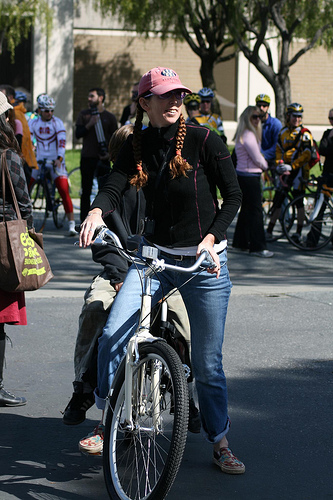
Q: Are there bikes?
A: Yes, there is a bike.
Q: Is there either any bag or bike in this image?
A: Yes, there is a bike.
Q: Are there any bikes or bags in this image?
A: Yes, there is a bike.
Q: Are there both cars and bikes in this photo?
A: No, there is a bike but no cars.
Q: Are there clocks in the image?
A: No, there are no clocks.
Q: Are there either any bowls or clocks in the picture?
A: No, there are no clocks or bowls.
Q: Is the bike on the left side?
A: Yes, the bike is on the left of the image.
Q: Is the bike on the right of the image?
A: No, the bike is on the left of the image.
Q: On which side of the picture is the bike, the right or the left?
A: The bike is on the left of the image.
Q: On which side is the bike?
A: The bike is on the left of the image.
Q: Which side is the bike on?
A: The bike is on the left of the image.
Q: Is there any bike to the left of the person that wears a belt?
A: Yes, there is a bike to the left of the person.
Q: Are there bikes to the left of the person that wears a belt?
A: Yes, there is a bike to the left of the person.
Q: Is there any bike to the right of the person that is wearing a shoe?
A: No, the bike is to the left of the person.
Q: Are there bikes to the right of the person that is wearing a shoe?
A: No, the bike is to the left of the person.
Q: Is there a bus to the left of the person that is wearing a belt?
A: No, there is a bike to the left of the person.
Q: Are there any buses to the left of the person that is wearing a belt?
A: No, there is a bike to the left of the person.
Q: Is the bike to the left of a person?
A: Yes, the bike is to the left of a person.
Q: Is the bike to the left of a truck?
A: No, the bike is to the left of a person.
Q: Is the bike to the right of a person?
A: No, the bike is to the left of a person.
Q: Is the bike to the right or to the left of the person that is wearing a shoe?
A: The bike is to the left of the person.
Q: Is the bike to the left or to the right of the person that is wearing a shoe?
A: The bike is to the left of the person.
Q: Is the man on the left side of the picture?
A: Yes, the man is on the left of the image.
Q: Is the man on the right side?
A: No, the man is on the left of the image.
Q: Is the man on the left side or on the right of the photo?
A: The man is on the left of the image.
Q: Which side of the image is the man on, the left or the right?
A: The man is on the left of the image.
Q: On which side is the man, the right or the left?
A: The man is on the left of the image.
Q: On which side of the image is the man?
A: The man is on the left of the image.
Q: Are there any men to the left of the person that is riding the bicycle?
A: Yes, there is a man to the left of the person.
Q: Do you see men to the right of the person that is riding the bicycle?
A: No, the man is to the left of the person.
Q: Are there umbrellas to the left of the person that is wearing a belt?
A: No, there is a man to the left of the person.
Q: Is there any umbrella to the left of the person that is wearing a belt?
A: No, there is a man to the left of the person.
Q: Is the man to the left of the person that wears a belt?
A: Yes, the man is to the left of the person.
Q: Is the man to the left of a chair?
A: No, the man is to the left of the person.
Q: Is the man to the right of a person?
A: No, the man is to the left of a person.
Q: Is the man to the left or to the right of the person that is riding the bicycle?
A: The man is to the left of the person.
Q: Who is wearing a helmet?
A: The man is wearing a helmet.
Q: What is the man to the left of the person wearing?
A: The man is wearing a helmet.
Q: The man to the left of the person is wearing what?
A: The man is wearing a helmet.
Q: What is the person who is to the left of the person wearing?
A: The man is wearing a helmet.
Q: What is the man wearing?
A: The man is wearing a helmet.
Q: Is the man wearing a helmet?
A: Yes, the man is wearing a helmet.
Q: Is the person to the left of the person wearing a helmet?
A: Yes, the man is wearing a helmet.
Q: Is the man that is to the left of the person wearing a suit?
A: No, the man is wearing a helmet.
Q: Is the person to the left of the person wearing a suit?
A: No, the man is wearing a helmet.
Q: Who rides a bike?
A: The man rides a bike.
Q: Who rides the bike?
A: The man rides a bike.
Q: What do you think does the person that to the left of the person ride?
A: The man rides a bike.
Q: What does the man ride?
A: The man rides a bike.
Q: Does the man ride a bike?
A: Yes, the man rides a bike.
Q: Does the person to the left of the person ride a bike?
A: Yes, the man rides a bike.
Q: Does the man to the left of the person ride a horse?
A: No, the man rides a bike.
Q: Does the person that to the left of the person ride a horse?
A: No, the man rides a bike.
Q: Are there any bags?
A: Yes, there is a bag.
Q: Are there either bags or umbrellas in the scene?
A: Yes, there is a bag.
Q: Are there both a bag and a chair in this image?
A: No, there is a bag but no chairs.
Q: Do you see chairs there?
A: No, there are no chairs.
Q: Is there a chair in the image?
A: No, there are no chairs.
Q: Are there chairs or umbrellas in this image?
A: No, there are no chairs or umbrellas.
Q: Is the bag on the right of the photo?
A: No, the bag is on the left of the image.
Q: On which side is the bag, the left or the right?
A: The bag is on the left of the image.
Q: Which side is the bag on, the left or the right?
A: The bag is on the left of the image.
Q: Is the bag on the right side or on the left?
A: The bag is on the left of the image.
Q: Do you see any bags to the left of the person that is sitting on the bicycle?
A: Yes, there is a bag to the left of the person.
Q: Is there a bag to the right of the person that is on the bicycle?
A: No, the bag is to the left of the person.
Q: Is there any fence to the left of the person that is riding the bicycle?
A: No, there is a bag to the left of the person.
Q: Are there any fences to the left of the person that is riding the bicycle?
A: No, there is a bag to the left of the person.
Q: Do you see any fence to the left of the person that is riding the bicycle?
A: No, there is a bag to the left of the person.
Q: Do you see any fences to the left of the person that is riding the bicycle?
A: No, there is a bag to the left of the person.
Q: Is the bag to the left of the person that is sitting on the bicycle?
A: Yes, the bag is to the left of the person.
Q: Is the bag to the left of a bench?
A: No, the bag is to the left of the person.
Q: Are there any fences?
A: No, there are no fences.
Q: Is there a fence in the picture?
A: No, there are no fences.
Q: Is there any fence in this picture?
A: No, there are no fences.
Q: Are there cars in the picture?
A: No, there are no cars.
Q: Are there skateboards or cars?
A: No, there are no cars or skateboards.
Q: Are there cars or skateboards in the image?
A: No, there are no cars or skateboards.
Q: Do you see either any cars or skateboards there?
A: No, there are no cars or skateboards.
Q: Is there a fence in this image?
A: No, there are no fences.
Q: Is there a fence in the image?
A: No, there are no fences.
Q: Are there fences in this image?
A: No, there are no fences.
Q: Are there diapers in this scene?
A: No, there are no diapers.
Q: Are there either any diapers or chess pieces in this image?
A: No, there are no diapers or chess pieces.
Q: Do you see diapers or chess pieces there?
A: No, there are no diapers or chess pieces.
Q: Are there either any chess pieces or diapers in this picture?
A: No, there are no diapers or chess pieces.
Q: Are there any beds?
A: No, there are no beds.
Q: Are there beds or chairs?
A: No, there are no beds or chairs.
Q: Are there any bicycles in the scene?
A: Yes, there is a bicycle.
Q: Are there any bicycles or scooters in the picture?
A: Yes, there is a bicycle.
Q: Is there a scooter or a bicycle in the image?
A: Yes, there is a bicycle.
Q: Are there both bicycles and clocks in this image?
A: No, there is a bicycle but no clocks.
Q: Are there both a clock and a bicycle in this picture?
A: No, there is a bicycle but no clocks.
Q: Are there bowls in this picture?
A: No, there are no bowls.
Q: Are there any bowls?
A: No, there are no bowls.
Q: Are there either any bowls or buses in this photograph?
A: No, there are no bowls or buses.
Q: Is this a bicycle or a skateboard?
A: This is a bicycle.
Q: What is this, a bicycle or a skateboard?
A: This is a bicycle.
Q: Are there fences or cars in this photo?
A: No, there are no fences or cars.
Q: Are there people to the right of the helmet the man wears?
A: Yes, there is a person to the right of the helmet.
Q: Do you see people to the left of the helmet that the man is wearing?
A: No, the person is to the right of the helmet.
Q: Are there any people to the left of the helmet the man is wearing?
A: No, the person is to the right of the helmet.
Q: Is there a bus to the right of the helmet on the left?
A: No, there is a person to the right of the helmet.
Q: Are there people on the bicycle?
A: Yes, there is a person on the bicycle.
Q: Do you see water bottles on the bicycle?
A: No, there is a person on the bicycle.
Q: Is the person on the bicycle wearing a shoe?
A: Yes, the person is wearing a shoe.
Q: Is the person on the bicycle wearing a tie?
A: No, the person is wearing a shoe.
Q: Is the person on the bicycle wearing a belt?
A: Yes, the person is wearing a belt.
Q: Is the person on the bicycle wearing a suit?
A: No, the person is wearing a belt.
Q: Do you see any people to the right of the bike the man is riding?
A: Yes, there is a person to the right of the bike.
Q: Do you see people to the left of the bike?
A: No, the person is to the right of the bike.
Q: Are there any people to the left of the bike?
A: No, the person is to the right of the bike.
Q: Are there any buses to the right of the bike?
A: No, there is a person to the right of the bike.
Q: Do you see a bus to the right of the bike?
A: No, there is a person to the right of the bike.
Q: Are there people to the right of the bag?
A: Yes, there is a person to the right of the bag.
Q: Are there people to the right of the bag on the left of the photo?
A: Yes, there is a person to the right of the bag.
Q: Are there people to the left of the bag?
A: No, the person is to the right of the bag.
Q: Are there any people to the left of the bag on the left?
A: No, the person is to the right of the bag.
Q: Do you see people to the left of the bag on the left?
A: No, the person is to the right of the bag.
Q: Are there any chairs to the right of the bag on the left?
A: No, there is a person to the right of the bag.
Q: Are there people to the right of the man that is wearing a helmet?
A: Yes, there is a person to the right of the man.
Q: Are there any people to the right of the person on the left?
A: Yes, there is a person to the right of the man.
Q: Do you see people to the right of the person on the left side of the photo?
A: Yes, there is a person to the right of the man.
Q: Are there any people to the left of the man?
A: No, the person is to the right of the man.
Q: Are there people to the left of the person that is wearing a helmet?
A: No, the person is to the right of the man.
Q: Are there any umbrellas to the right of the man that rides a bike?
A: No, there is a person to the right of the man.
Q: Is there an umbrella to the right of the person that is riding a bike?
A: No, there is a person to the right of the man.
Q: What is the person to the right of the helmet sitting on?
A: The person is sitting on the bicycle.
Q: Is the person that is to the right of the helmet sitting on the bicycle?
A: Yes, the person is sitting on the bicycle.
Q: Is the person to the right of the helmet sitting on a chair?
A: No, the person is sitting on the bicycle.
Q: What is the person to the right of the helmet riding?
A: The person is riding the bicycle.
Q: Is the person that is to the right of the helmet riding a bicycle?
A: Yes, the person is riding a bicycle.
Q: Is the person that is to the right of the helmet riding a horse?
A: No, the person is riding a bicycle.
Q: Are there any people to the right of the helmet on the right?
A: No, the person is to the left of the helmet.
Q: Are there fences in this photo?
A: No, there are no fences.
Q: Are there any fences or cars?
A: No, there are no fences or cars.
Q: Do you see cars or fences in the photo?
A: No, there are no fences or cars.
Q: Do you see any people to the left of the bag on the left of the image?
A: No, the person is to the right of the bag.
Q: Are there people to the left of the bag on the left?
A: No, the person is to the right of the bag.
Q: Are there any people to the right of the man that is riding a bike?
A: Yes, there is a person to the right of the man.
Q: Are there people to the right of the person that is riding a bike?
A: Yes, there is a person to the right of the man.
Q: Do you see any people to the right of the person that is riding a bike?
A: Yes, there is a person to the right of the man.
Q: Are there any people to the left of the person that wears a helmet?
A: No, the person is to the right of the man.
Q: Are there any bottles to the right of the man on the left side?
A: No, there is a person to the right of the man.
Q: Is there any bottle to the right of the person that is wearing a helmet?
A: No, there is a person to the right of the man.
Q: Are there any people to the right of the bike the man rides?
A: Yes, there is a person to the right of the bike.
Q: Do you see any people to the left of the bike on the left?
A: No, the person is to the right of the bike.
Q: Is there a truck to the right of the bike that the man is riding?
A: No, there is a person to the right of the bike.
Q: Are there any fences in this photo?
A: No, there are no fences.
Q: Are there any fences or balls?
A: No, there are no fences or balls.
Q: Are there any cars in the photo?
A: No, there are no cars.